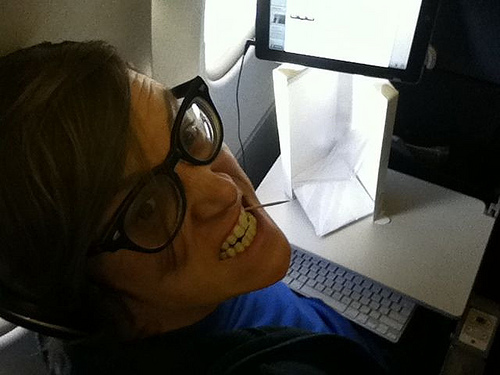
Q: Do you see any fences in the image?
A: No, there are no fences.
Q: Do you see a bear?
A: No, there are no bears.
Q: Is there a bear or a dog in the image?
A: No, there are no bears or dogs.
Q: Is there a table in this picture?
A: Yes, there is a table.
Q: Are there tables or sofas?
A: Yes, there is a table.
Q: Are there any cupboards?
A: No, there are no cupboards.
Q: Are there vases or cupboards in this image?
A: No, there are no cupboards or vases.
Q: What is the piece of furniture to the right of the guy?
A: The piece of furniture is a table.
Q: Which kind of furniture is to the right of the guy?
A: The piece of furniture is a table.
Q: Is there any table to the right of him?
A: Yes, there is a table to the right of the guy.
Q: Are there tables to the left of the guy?
A: No, the table is to the right of the guy.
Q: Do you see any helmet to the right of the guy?
A: No, there is a table to the right of the guy.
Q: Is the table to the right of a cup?
A: No, the table is to the right of a guy.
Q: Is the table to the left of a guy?
A: No, the table is to the right of a guy.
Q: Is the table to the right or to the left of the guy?
A: The table is to the right of the guy.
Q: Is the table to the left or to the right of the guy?
A: The table is to the right of the guy.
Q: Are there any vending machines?
A: No, there are no vending machines.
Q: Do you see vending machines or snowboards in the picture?
A: No, there are no vending machines or snowboards.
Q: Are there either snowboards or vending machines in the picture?
A: No, there are no vending machines or snowboards.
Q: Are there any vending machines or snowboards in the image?
A: No, there are no vending machines or snowboards.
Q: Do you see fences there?
A: No, there are no fences.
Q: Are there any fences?
A: No, there are no fences.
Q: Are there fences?
A: No, there are no fences.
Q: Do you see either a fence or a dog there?
A: No, there are no fences or dogs.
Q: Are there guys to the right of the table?
A: No, the guy is to the left of the table.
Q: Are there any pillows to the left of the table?
A: No, there is a guy to the left of the table.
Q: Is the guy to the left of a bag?
A: No, the guy is to the left of the table.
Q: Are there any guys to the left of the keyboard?
A: Yes, there is a guy to the left of the keyboard.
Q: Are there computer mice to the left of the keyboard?
A: No, there is a guy to the left of the keyboard.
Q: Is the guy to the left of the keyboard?
A: Yes, the guy is to the left of the keyboard.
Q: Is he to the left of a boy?
A: No, the guy is to the left of the keyboard.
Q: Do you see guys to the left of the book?
A: Yes, there is a guy to the left of the book.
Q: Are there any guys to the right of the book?
A: No, the guy is to the left of the book.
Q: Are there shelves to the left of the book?
A: No, there is a guy to the left of the book.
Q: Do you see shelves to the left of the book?
A: No, there is a guy to the left of the book.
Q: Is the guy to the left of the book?
A: Yes, the guy is to the left of the book.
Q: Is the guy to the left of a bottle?
A: No, the guy is to the left of the book.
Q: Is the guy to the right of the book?
A: No, the guy is to the left of the book.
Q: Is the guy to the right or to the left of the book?
A: The guy is to the left of the book.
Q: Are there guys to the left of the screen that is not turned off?
A: Yes, there is a guy to the left of the screen.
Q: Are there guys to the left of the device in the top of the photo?
A: Yes, there is a guy to the left of the screen.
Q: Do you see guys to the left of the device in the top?
A: Yes, there is a guy to the left of the screen.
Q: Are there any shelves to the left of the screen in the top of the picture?
A: No, there is a guy to the left of the screen.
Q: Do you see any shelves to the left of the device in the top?
A: No, there is a guy to the left of the screen.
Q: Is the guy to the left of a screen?
A: Yes, the guy is to the left of a screen.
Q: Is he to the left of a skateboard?
A: No, the guy is to the left of a screen.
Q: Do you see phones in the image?
A: Yes, there is a phone.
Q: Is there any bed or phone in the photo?
A: Yes, there is a phone.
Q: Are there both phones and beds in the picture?
A: No, there is a phone but no beds.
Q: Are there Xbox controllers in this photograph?
A: No, there are no Xbox controllers.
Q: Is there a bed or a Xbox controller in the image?
A: No, there are no Xbox controllers or beds.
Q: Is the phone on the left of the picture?
A: Yes, the phone is on the left of the image.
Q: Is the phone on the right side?
A: No, the phone is on the left of the image.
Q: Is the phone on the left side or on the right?
A: The phone is on the left of the image.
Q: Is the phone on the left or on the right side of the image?
A: The phone is on the left of the image.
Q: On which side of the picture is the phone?
A: The phone is on the left of the image.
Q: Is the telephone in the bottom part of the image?
A: Yes, the telephone is in the bottom of the image.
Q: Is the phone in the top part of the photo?
A: No, the phone is in the bottom of the image.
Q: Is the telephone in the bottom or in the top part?
A: The telephone is in the bottom of the image.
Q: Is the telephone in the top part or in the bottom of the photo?
A: The telephone is in the bottom of the image.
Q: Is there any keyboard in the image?
A: Yes, there is a keyboard.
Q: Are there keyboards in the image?
A: Yes, there is a keyboard.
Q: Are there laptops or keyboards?
A: Yes, there is a keyboard.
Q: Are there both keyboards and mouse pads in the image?
A: No, there is a keyboard but no mouse pads.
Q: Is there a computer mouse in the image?
A: No, there are no computer mice.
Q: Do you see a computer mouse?
A: No, there are no computer mice.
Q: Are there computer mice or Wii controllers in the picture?
A: No, there are no computer mice or Wii controllers.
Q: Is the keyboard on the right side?
A: Yes, the keyboard is on the right of the image.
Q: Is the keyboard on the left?
A: No, the keyboard is on the right of the image.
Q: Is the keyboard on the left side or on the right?
A: The keyboard is on the right of the image.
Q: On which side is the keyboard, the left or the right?
A: The keyboard is on the right of the image.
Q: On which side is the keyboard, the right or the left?
A: The keyboard is on the right of the image.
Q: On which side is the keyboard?
A: The keyboard is on the right of the image.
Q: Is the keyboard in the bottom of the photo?
A: Yes, the keyboard is in the bottom of the image.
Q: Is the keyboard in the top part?
A: No, the keyboard is in the bottom of the image.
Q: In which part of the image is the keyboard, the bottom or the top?
A: The keyboard is in the bottom of the image.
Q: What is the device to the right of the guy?
A: The device is a keyboard.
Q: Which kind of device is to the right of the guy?
A: The device is a keyboard.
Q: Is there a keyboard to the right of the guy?
A: Yes, there is a keyboard to the right of the guy.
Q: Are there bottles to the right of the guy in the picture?
A: No, there is a keyboard to the right of the guy.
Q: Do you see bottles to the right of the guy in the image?
A: No, there is a keyboard to the right of the guy.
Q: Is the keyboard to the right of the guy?
A: Yes, the keyboard is to the right of the guy.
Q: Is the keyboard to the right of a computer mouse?
A: No, the keyboard is to the right of the guy.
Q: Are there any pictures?
A: No, there are no pictures.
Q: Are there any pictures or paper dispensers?
A: No, there are no pictures or paper dispensers.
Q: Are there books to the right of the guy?
A: Yes, there is a book to the right of the guy.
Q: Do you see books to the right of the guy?
A: Yes, there is a book to the right of the guy.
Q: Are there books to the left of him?
A: No, the book is to the right of the guy.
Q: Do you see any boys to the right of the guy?
A: No, there is a book to the right of the guy.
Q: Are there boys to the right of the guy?
A: No, there is a book to the right of the guy.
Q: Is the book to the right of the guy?
A: Yes, the book is to the right of the guy.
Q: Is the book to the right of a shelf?
A: No, the book is to the right of the guy.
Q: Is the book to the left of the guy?
A: No, the book is to the right of the guy.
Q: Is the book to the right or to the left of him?
A: The book is to the right of the guy.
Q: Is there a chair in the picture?
A: Yes, there is a chair.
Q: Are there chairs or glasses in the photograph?
A: Yes, there is a chair.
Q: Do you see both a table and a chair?
A: Yes, there are both a chair and a table.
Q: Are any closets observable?
A: No, there are no closets.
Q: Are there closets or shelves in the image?
A: No, there are no closets or shelves.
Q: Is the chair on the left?
A: Yes, the chair is on the left of the image.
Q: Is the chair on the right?
A: No, the chair is on the left of the image.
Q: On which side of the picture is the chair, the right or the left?
A: The chair is on the left of the image.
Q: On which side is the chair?
A: The chair is on the left of the image.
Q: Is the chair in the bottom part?
A: Yes, the chair is in the bottom of the image.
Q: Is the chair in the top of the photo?
A: No, the chair is in the bottom of the image.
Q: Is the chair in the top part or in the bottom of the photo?
A: The chair is in the bottom of the image.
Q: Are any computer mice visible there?
A: No, there are no computer mice.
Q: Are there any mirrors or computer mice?
A: No, there are no computer mice or mirrors.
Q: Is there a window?
A: Yes, there is a window.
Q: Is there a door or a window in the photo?
A: Yes, there is a window.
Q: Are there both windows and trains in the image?
A: No, there is a window but no trains.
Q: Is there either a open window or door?
A: Yes, there is an open window.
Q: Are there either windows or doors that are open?
A: Yes, the window is open.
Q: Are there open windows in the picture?
A: Yes, there is an open window.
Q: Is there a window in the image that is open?
A: Yes, there is a window that is open.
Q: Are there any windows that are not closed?
A: Yes, there is a open window.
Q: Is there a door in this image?
A: No, there are no doors.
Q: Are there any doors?
A: No, there are no doors.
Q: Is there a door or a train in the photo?
A: No, there are no doors or trains.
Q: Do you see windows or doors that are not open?
A: No, there is a window but it is open.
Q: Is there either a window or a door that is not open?
A: No, there is a window but it is open.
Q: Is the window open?
A: Yes, the window is open.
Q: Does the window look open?
A: Yes, the window is open.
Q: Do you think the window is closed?
A: No, the window is open.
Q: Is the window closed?
A: No, the window is open.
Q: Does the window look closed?
A: No, the window is open.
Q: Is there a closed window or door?
A: No, there is a window but it is open.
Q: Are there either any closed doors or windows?
A: No, there is a window but it is open.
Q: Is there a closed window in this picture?
A: No, there is a window but it is open.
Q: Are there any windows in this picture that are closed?
A: No, there is a window but it is open.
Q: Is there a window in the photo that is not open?
A: No, there is a window but it is open.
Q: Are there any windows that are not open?
A: No, there is a window but it is open.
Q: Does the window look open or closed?
A: The window is open.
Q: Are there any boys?
A: No, there are no boys.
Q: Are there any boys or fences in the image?
A: No, there are no boys or fences.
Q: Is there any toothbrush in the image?
A: No, there are no toothbrushes.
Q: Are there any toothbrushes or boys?
A: No, there are no toothbrushes or boys.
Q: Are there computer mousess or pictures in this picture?
A: No, there are no pictures or computer mousess.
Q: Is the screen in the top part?
A: Yes, the screen is in the top of the image.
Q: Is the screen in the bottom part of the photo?
A: No, the screen is in the top of the image.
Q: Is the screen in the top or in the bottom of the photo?
A: The screen is in the top of the image.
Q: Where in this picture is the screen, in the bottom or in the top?
A: The screen is in the top of the image.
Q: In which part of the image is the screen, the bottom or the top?
A: The screen is in the top of the image.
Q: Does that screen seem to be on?
A: Yes, the screen is on.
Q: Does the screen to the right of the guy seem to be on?
A: Yes, the screen is on.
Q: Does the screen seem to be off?
A: No, the screen is on.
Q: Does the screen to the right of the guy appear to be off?
A: No, the screen is on.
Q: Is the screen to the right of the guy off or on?
A: The screen is on.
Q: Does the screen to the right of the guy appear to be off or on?
A: The screen is on.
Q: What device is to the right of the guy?
A: The device is a screen.